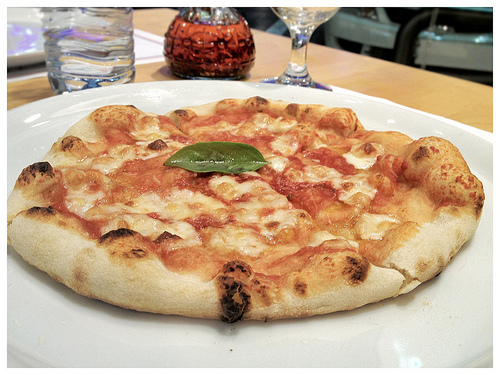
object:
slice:
[9, 104, 400, 320]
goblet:
[261, 9, 360, 79]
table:
[10, 9, 489, 367]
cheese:
[339, 149, 380, 171]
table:
[356, 46, 497, 130]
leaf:
[165, 136, 264, 172]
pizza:
[19, 94, 477, 306]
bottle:
[161, 8, 261, 82]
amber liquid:
[165, 21, 256, 72]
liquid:
[28, 19, 145, 81]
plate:
[6, 80, 494, 374]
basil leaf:
[162, 141, 272, 174]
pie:
[7, 95, 484, 321]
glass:
[259, 5, 340, 92]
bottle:
[43, 15, 132, 82]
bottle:
[245, 7, 422, 92]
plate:
[7, 275, 499, 365]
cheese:
[53, 109, 413, 266]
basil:
[158, 136, 273, 189]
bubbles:
[402, 135, 484, 204]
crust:
[18, 240, 490, 320]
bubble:
[215, 264, 248, 326]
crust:
[11, 95, 483, 327]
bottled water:
[35, 5, 146, 90]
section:
[84, 164, 260, 324]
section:
[268, 129, 487, 303]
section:
[49, 86, 271, 224]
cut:
[249, 164, 456, 303]